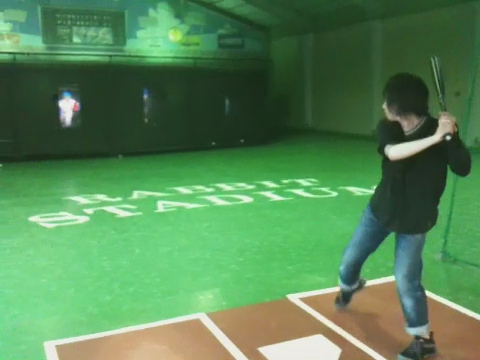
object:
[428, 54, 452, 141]
baseball bat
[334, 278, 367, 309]
shoe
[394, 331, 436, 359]
shoe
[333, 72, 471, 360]
boy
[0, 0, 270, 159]
wall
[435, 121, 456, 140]
hands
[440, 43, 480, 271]
batting cage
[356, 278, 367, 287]
heel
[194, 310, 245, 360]
white line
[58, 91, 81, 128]
pitcher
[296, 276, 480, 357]
dirt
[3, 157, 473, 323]
floor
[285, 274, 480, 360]
batters box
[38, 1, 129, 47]
scoreboard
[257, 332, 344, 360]
base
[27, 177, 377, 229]
astroturf writing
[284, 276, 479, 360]
square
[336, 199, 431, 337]
blue jeans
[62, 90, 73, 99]
helmet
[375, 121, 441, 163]
arm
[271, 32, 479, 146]
wall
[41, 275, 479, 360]
baseball diamond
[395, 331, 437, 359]
tennis shoes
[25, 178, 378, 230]
rabbit stadium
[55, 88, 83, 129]
pitchig machie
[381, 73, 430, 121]
bo has hair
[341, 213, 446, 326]
pats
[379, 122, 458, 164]
bo has ski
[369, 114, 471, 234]
shirt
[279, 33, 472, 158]
gree wall